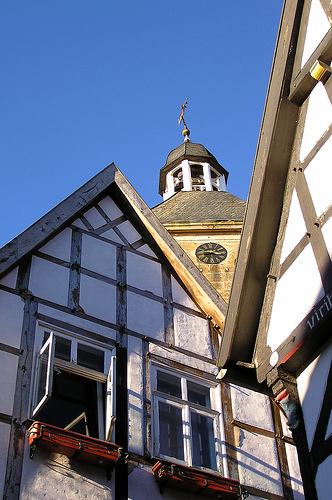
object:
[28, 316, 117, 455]
window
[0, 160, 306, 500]
building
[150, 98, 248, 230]
tower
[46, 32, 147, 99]
sky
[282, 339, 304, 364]
paint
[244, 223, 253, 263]
paint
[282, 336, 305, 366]
trimming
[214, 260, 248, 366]
trimming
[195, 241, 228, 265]
clock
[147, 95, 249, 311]
building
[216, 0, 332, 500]
building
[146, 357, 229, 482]
window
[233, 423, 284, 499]
tiles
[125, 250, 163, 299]
tiles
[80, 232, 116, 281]
tiles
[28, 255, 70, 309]
tiles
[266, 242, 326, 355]
tiles